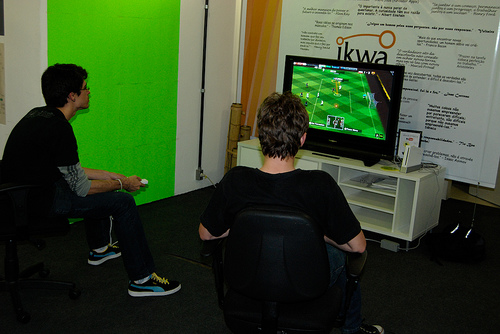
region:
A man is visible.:
[176, 108, 351, 294]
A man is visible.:
[219, 126, 319, 324]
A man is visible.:
[263, 160, 336, 327]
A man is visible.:
[252, 136, 313, 281]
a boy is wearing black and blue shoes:
[129, 281, 179, 295]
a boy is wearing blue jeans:
[118, 210, 152, 265]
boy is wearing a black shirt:
[247, 181, 304, 203]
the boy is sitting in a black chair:
[237, 220, 300, 297]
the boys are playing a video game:
[309, 69, 371, 114]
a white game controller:
[136, 175, 153, 192]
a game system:
[399, 143, 424, 173]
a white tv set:
[365, 170, 404, 221]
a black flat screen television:
[281, 52, 408, 115]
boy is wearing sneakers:
[356, 320, 375, 332]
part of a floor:
[159, 302, 177, 315]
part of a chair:
[256, 239, 294, 283]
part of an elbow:
[343, 225, 361, 256]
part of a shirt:
[311, 199, 336, 234]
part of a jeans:
[346, 301, 361, 326]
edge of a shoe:
[121, 266, 161, 303]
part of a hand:
[121, 176, 149, 211]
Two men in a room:
[1, 72, 462, 331]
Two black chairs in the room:
[0, 150, 406, 326]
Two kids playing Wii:
[2, 32, 424, 326]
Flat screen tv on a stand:
[240, 32, 414, 174]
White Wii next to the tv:
[396, 137, 434, 180]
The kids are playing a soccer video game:
[278, 44, 406, 157]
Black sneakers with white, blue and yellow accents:
[79, 234, 190, 304]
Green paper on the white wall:
[39, 0, 191, 197]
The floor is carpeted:
[5, 175, 493, 330]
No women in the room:
[0, 1, 487, 328]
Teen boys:
[48, 58, 98, 113]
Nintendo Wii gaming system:
[392, 141, 432, 176]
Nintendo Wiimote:
[121, 175, 154, 185]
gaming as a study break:
[26, 32, 419, 255]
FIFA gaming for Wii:
[272, 46, 412, 143]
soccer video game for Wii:
[261, 51, 422, 152]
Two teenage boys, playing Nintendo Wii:
[26, 43, 371, 238]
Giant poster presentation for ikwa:
[425, 85, 485, 135]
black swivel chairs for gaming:
[213, 235, 435, 326]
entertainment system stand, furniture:
[225, 135, 470, 254]